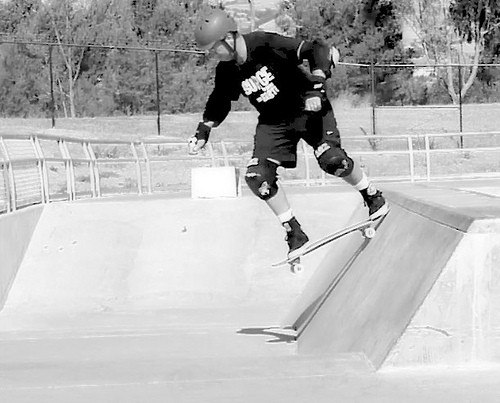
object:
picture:
[0, 0, 499, 403]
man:
[186, 6, 389, 263]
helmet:
[192, 13, 239, 51]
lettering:
[240, 65, 280, 103]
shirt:
[201, 31, 343, 123]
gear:
[292, 261, 306, 273]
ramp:
[294, 185, 474, 366]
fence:
[0, 43, 498, 150]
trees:
[387, 0, 500, 105]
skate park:
[0, 122, 500, 403]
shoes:
[283, 223, 312, 258]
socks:
[275, 209, 299, 225]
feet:
[363, 191, 390, 219]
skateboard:
[276, 214, 384, 269]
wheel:
[291, 259, 304, 273]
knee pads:
[246, 157, 281, 200]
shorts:
[249, 115, 341, 165]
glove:
[192, 122, 210, 143]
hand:
[185, 131, 211, 155]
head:
[192, 11, 237, 61]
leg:
[244, 132, 302, 229]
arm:
[285, 36, 334, 92]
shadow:
[236, 237, 373, 342]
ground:
[0, 175, 499, 401]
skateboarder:
[188, 6, 388, 263]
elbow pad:
[330, 43, 341, 67]